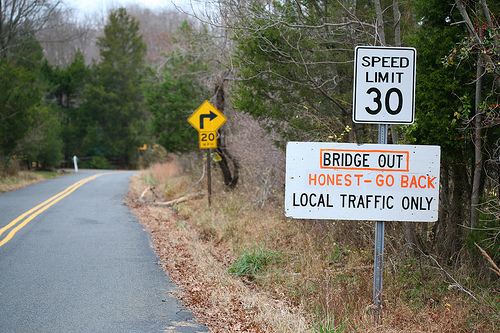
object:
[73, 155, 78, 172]
mail box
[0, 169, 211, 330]
road side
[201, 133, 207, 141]
number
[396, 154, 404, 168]
letter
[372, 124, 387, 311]
pole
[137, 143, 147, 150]
sign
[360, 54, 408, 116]
speed limit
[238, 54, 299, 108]
leaves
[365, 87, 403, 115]
number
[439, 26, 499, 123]
leaves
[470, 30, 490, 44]
colors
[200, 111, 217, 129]
arrow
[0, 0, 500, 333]
background.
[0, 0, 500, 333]
bushes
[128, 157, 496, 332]
grass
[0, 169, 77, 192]
grass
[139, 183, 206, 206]
log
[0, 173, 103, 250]
line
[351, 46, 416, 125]
road sign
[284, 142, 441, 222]
road sign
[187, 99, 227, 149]
road sign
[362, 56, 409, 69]
black writing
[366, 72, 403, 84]
black writing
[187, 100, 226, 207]
post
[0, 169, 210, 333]
road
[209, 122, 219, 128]
yellow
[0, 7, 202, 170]
pin tree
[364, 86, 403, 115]
writting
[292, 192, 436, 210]
writting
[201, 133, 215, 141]
writting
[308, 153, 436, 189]
writting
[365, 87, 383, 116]
part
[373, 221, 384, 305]
part